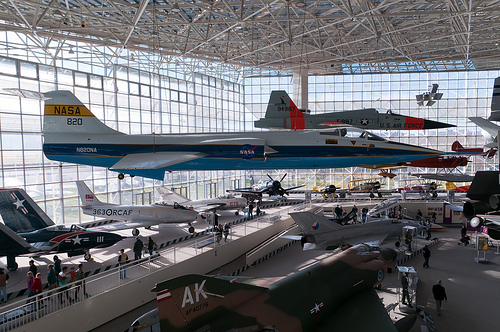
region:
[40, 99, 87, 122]
nasa painted on a jet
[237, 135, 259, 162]
the nasa logo on a jet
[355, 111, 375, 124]
a jet with the united states logo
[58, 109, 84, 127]
the numbers 820 painted black onto a jet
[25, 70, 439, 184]
a white and blue nasa jet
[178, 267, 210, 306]
ak painted onto a jet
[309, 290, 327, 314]
the united states logo painted on a jet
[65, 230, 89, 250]
the united states logo painted on a jet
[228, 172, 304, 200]
an airplane with a front propellor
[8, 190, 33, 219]
a united states logo painted on a jet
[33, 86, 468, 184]
plane with NASA on yellow stripe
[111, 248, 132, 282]
person in yellow shirt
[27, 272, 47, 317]
person wearing red shirt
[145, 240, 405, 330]
brown plane with AK on it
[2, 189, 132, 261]
black plane with stars on it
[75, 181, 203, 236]
white plane with red lettering on tail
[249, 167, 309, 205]
plane with propeller in full view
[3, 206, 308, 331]
the white walkway of the plane hangar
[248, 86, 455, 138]
plane with red stripes and black nose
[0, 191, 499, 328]
the floor of the hangar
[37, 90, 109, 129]
letters and numbers on a tail of a plane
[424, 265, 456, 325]
a person walking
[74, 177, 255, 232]
two small planes parked next to each other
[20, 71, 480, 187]
two planes hanging froma ceiling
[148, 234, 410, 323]
camouflage aircraft with the letters AK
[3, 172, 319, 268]
Small planes parked next to each other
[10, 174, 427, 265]
Small planes parked in a showroom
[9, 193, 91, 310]
a group of people standing next to a plane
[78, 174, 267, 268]
people in a showroom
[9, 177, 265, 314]
people in an airplane showroom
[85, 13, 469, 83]
ceiling at the top of a showroom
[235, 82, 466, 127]
orange and gray airplane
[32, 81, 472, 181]
two airplanes hanging from a ceiling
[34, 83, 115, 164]
Nasa written on the tail of a plane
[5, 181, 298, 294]
people inside a plane museum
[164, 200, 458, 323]
plane museum floor with old planes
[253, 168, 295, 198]
propeller on an old plane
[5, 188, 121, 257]
small plane in a showroom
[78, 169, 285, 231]
different old planes in a museum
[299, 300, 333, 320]
logo on the side of a plane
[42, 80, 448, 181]
NASA jet hanging on display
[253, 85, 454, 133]
US Air Force jet hanging on display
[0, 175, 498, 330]
various types of airplanes on display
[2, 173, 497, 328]
various kinds of airplanes on the ground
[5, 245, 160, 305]
vistors walking and observing the planes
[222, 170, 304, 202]
propeller plane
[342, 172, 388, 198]
a bi-plane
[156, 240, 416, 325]
a brown and black plane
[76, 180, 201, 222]
a white plane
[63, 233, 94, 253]
stars and stripes on the side of a plane